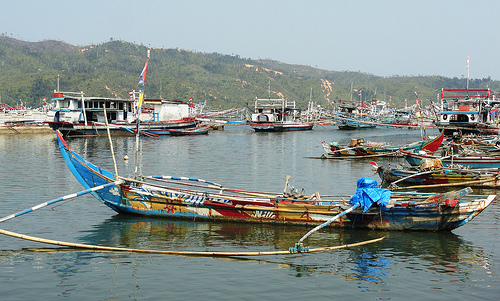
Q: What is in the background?
A: A white boat.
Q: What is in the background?
A: A green hill.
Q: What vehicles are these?
A: Boats.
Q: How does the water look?
A: Calm.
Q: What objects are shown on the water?
A: Boats.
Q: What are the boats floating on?
A: Water.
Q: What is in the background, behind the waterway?
A: A hill.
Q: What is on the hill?
A: Green trees.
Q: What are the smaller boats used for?
A: Fishing.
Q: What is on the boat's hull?
A: Painted designs.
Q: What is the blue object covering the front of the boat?
A: A tarp.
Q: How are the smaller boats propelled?
A: Paddles.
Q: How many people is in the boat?
A: No one.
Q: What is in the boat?
A: Nothing is in the boat.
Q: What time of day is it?
A: It is in the afternoon.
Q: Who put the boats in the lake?
A: The community.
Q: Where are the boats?
A: In the lake.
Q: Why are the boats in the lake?
A: For fishing.